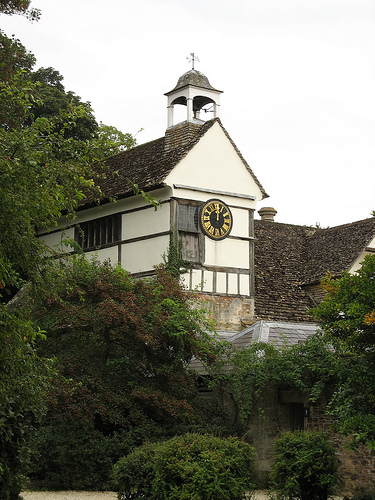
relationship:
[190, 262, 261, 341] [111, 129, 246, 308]
wall on side of a building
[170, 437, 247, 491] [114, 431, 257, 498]
leaves on bush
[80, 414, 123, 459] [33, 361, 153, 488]
leaves on bush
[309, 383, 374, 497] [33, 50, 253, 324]
wall of building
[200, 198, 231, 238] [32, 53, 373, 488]
clock on building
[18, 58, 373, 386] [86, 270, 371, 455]
building by trees